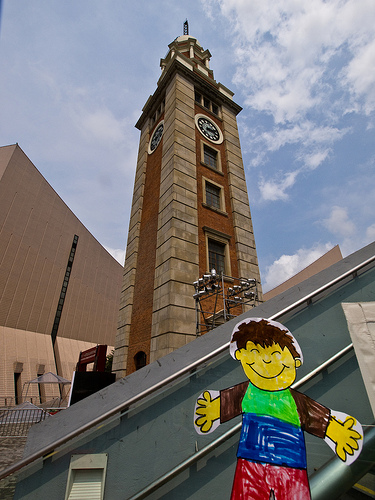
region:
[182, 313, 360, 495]
a piece of paper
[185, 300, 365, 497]
a piece of paper of human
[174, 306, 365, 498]
a human figure on a piece of paper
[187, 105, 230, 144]
clock on a tower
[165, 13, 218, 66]
roof of a tower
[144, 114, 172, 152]
clock on a tower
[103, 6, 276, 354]
a clock tower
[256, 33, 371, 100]
sky full of clouds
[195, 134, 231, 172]
the window of a clock tower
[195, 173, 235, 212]
windows of a clock tower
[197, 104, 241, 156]
clock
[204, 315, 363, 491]
paper man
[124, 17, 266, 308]
brown tower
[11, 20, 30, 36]
white clouds in blue sky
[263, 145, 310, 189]
white clouds in blue sky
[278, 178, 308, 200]
white clouds in blue sky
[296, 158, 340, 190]
white clouds in blue sky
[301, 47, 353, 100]
white clouds in blue sky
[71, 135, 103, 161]
white clouds in blue sky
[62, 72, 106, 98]
white clouds in blue sky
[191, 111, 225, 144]
clock on the tower.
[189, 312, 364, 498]
Paper character in the forefront.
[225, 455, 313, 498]
Red shorts on character.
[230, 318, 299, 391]
Brown hair on the head.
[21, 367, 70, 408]
Canopy in the background.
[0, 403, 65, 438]
Metal fence in the background.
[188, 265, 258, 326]
Lights on the structure.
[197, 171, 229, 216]
Door in the building.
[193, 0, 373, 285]
White clouds in the sky.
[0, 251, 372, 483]
Metal bar down the structure.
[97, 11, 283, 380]
the building is brown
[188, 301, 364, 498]
person made of paper on steps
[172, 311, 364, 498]
colored marker on person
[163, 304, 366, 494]
person's face and hands are yellow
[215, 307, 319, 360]
person's hair is brown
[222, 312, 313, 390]
the person is smiling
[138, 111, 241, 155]
clocks on the building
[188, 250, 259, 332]
structure made of metal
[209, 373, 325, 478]
person's shirt is brown green and blue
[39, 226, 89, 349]
black part on building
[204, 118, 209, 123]
roman numeral on clock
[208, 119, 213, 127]
roman numeral on clock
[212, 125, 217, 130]
roman numeral on clock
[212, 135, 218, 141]
roman numeral on clock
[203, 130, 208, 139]
roman numeral on clock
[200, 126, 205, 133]
roman numeral on clock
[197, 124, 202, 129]
roman numeral on clock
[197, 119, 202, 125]
roman numeral on clock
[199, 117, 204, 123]
roman numeral on clock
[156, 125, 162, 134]
roman numeral on clock